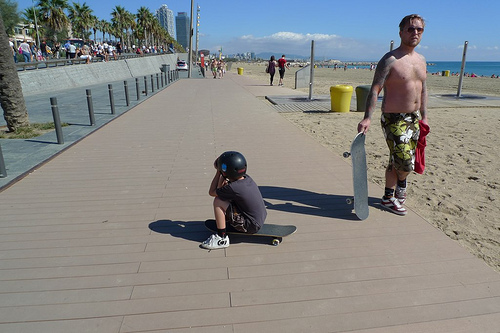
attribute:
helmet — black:
[214, 150, 248, 181]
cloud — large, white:
[230, 24, 367, 66]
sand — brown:
[226, 59, 499, 275]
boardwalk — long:
[7, 57, 497, 331]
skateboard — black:
[345, 110, 433, 249]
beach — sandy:
[228, 61, 498, 267]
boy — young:
[198, 150, 273, 250]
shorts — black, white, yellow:
[379, 110, 426, 172]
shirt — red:
[410, 117, 430, 174]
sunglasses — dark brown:
[392, 16, 437, 43]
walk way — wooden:
[89, 135, 198, 303]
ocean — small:
[428, 59, 499, 76]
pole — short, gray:
[46, 92, 79, 152]